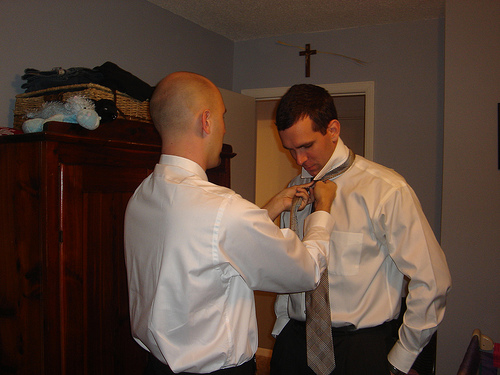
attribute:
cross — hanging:
[294, 32, 352, 126]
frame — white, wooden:
[243, 78, 373, 160]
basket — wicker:
[13, 81, 153, 125]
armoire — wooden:
[5, 113, 234, 370]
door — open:
[236, 80, 376, 200]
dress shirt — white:
[120, 152, 331, 368]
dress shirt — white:
[267, 137, 449, 371]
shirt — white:
[266, 139, 454, 371]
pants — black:
[266, 319, 404, 371]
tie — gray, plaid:
[297, 147, 360, 367]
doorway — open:
[187, 75, 375, 363]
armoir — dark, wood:
[4, 115, 237, 370]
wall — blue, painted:
[3, 2, 230, 124]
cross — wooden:
[295, 40, 320, 76]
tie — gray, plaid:
[280, 146, 355, 369]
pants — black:
[271, 307, 430, 372]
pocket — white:
[322, 223, 367, 277]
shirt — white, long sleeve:
[121, 150, 331, 368]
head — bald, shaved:
[147, 69, 227, 169]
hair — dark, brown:
[272, 81, 340, 132]